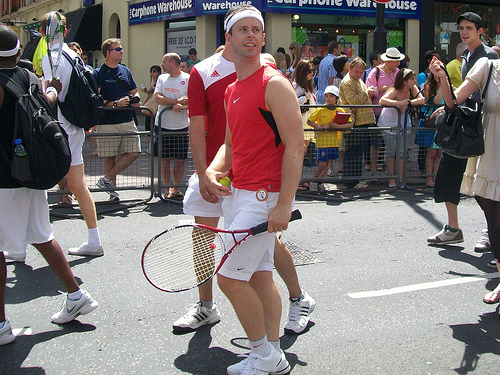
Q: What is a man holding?
A: Tennis racket.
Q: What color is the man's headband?
A: White.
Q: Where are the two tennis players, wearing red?
A: In the center of the street, side-by-side.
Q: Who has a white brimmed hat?
A: A person in a pink top.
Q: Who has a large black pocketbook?
A: A woman in a ruffled, buff colored dress.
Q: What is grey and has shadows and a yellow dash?
A: The street.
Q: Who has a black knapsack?
A: A brunette male, wearing white, knee-length shorts and a dark jacket.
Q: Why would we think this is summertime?
A: Many people are wearing short sleeves, no sleeves and shorts.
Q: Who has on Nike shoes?
A: A man with a black knapsack and headband.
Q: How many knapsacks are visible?
A: Two.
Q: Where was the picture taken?
A: On a street.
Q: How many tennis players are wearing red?
A: 2.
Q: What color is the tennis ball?
A: Yellow.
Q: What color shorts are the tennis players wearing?
A: White.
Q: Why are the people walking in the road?
A: For a parade.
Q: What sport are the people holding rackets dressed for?
A: Tennis.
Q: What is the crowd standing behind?
A: Metal barricade.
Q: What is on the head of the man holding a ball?
A: A headband.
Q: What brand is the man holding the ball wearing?
A: Nike.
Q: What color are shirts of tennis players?
A: Red.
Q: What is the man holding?
A: A tennis racket.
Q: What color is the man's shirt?
A: Red.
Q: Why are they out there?
A: To play tennis.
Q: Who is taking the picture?
A: A friend of the tennis player.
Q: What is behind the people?
A: A warehouse.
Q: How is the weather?
A: Sunny and clear.